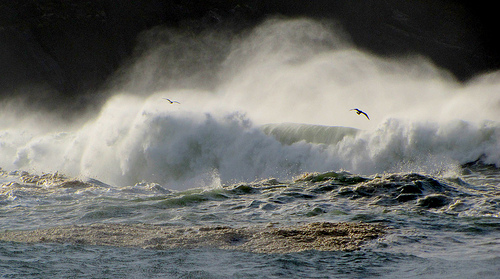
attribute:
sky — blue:
[0, 2, 498, 127]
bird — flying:
[345, 107, 370, 117]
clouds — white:
[0, 1, 493, 122]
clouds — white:
[171, 40, 360, 146]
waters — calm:
[3, 199, 498, 277]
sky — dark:
[0, 0, 499, 104]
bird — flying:
[347, 101, 374, 123]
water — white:
[85, 51, 317, 181]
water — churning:
[239, 162, 466, 248]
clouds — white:
[188, 44, 373, 156]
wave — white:
[0, 93, 499, 193]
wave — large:
[1, 18, 498, 189]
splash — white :
[90, 79, 467, 208]